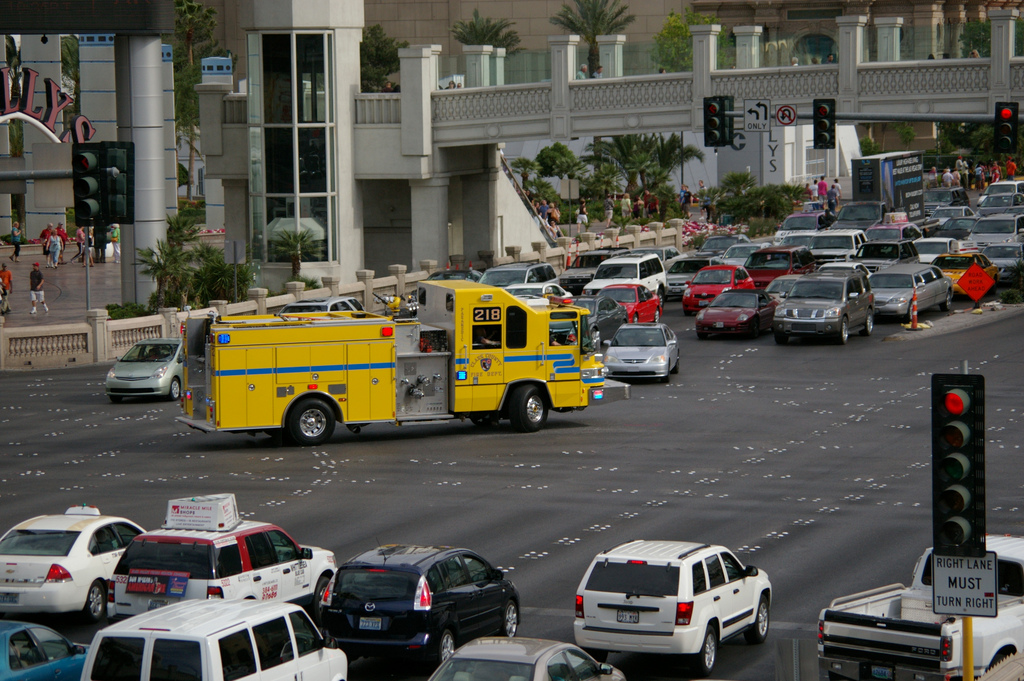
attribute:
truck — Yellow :
[175, 271, 635, 445]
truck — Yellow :
[176, 279, 609, 442]